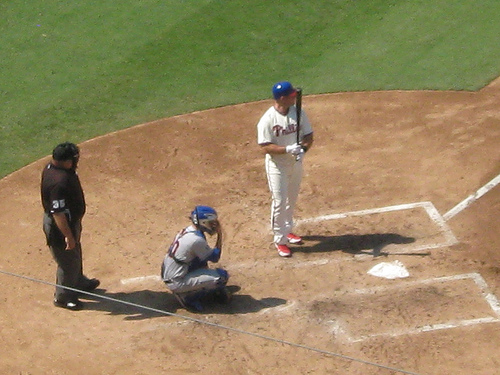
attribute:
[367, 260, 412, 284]
plate — white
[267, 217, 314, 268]
cleats — red, white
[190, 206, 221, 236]
catcher's helmet — blue, plastic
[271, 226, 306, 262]
shoes — red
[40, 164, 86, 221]
shirt — black, short sleeve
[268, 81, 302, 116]
hat — black, metal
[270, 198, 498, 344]
lines —  white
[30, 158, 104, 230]
shirt — black, cotton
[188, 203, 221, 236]
catcher's helmet — blue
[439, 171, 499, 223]
line — white, base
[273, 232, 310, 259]
sneakers — red, white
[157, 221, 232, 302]
baseball uniform — blue, red, grey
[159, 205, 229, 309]
uniform — grey, blue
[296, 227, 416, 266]
shadow — batter's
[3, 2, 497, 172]
grass — green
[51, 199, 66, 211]
number —  35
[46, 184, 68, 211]
sleeve —  his 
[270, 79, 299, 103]
helmet — blue, red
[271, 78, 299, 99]
helmet — blue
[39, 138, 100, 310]
man — in black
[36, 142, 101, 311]
baseball umpire — heavy set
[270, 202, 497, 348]
chalk — grey